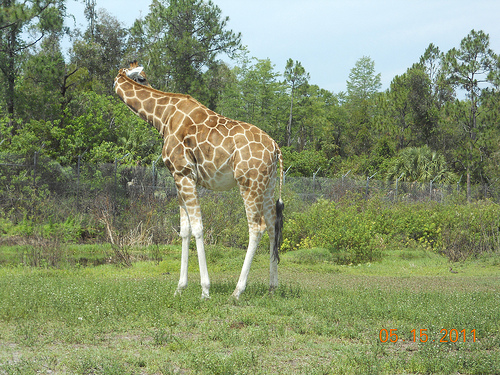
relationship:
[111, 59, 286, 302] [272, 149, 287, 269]
giraffe has long tail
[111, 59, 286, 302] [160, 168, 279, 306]
giraffe has long legs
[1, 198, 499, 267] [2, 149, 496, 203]
bushes in front of fencing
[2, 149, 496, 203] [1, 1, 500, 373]
fencing securing giraffe's habitat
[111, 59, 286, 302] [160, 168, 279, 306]
giraffe has white legs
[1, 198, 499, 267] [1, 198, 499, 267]
bushes with bushes